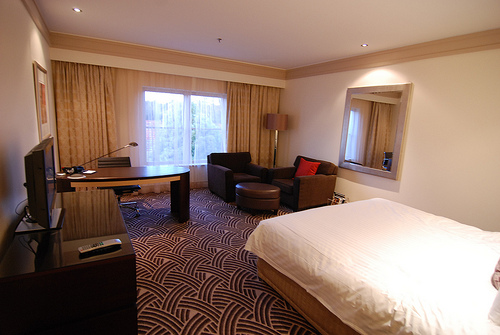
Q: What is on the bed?
A: Nothing.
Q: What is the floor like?
A: Decorated.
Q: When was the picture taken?
A: During the day.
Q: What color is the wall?
A: White.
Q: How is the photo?
A: Clear.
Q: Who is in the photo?
A: Nobody.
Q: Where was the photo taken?
A: Hotel.